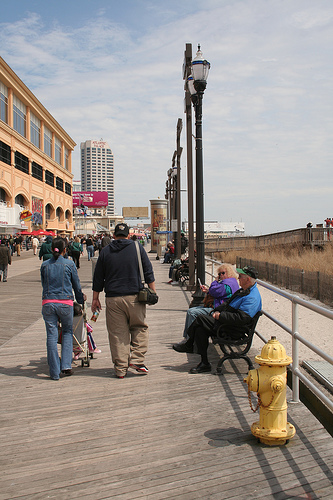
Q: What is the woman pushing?
A: A stroller.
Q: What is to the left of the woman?
A: A tall building.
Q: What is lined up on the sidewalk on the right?
A: Lamp posts.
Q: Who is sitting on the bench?
A: Man and woman.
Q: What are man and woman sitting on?
A: Bench.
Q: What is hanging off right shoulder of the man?
A: Shoulder bag.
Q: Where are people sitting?
A: Benches.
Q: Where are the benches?
A: On the sidewalk.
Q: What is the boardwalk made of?
A: Wood.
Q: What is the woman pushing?
A: A stroller.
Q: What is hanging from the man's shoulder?
A: A purse.